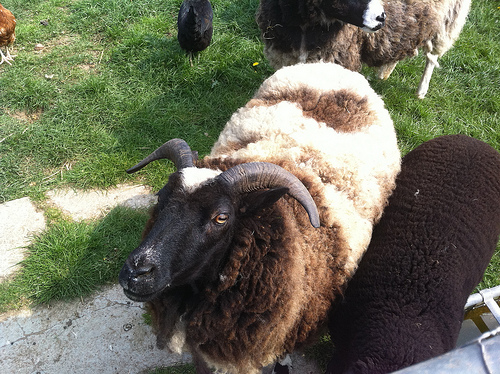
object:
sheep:
[116, 58, 402, 373]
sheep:
[325, 132, 499, 373]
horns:
[125, 137, 197, 175]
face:
[117, 167, 238, 302]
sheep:
[250, 0, 473, 101]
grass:
[51, 35, 92, 64]